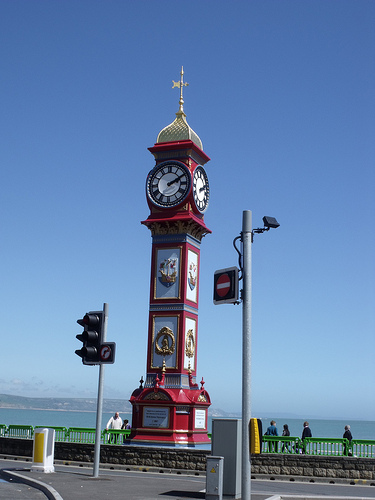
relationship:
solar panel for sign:
[262, 215, 280, 228] [212, 266, 238, 303]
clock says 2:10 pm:
[143, 159, 192, 209] [167, 173, 187, 190]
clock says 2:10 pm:
[192, 164, 209, 215] [196, 177, 208, 191]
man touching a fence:
[105, 411, 123, 444] [1, 422, 374, 461]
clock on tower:
[143, 159, 192, 209] [126, 59, 216, 452]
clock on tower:
[192, 164, 209, 215] [126, 59, 216, 452]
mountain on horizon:
[1, 392, 373, 434] [8, 11, 373, 451]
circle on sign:
[215, 273, 230, 295] [212, 266, 238, 303]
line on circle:
[215, 282, 233, 292] [215, 273, 230, 295]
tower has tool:
[126, 59, 216, 452] [158, 61, 200, 119]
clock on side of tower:
[192, 162, 209, 212] [141, 64, 206, 388]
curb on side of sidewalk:
[125, 462, 180, 477] [107, 450, 210, 484]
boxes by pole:
[207, 402, 250, 496] [225, 199, 260, 492]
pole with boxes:
[225, 199, 260, 492] [207, 402, 250, 496]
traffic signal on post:
[99, 341, 114, 363] [91, 364, 104, 477]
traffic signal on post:
[99, 341, 114, 363] [101, 303, 108, 342]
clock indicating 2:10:
[192, 164, 209, 215] [196, 179, 215, 199]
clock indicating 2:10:
[143, 159, 192, 209] [161, 168, 190, 187]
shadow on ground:
[158, 485, 206, 496] [0, 461, 374, 498]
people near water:
[342, 423, 355, 457] [6, 407, 372, 434]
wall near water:
[2, 436, 374, 482] [0, 406, 373, 453]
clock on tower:
[143, 159, 192, 209] [121, 110, 211, 451]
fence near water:
[1, 422, 374, 461] [0, 406, 373, 453]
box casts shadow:
[197, 451, 227, 499] [154, 478, 218, 497]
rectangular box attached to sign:
[261, 213, 279, 230] [209, 261, 240, 304]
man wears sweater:
[105, 411, 123, 445] [107, 415, 124, 432]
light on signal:
[76, 313, 101, 330] [79, 310, 106, 366]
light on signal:
[74, 329, 97, 345] [79, 310, 106, 366]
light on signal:
[73, 344, 99, 362] [79, 310, 106, 366]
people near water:
[260, 416, 362, 458] [5, 403, 373, 462]